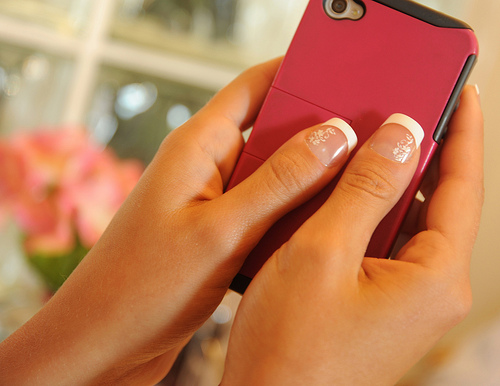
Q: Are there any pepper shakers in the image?
A: No, there are no pepper shakers.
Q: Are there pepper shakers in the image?
A: No, there are no pepper shakers.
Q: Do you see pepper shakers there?
A: No, there are no pepper shakers.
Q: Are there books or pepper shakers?
A: No, there are no pepper shakers or books.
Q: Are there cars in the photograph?
A: No, there are no cars.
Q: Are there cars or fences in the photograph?
A: No, there are no cars or fences.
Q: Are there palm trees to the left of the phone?
A: Yes, there is a palm tree to the left of the phone.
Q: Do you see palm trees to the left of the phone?
A: Yes, there is a palm tree to the left of the phone.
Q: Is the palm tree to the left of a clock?
A: No, the palm tree is to the left of the phone.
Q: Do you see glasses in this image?
A: No, there are no glasses.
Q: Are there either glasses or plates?
A: No, there are no glasses or plates.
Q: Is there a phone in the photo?
A: Yes, there is a phone.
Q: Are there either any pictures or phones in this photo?
A: Yes, there is a phone.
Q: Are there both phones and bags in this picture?
A: No, there is a phone but no bags.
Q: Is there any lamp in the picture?
A: No, there are no lamps.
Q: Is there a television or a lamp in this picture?
A: No, there are no lamps or televisions.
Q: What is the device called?
A: The device is a phone.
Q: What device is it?
A: The device is a phone.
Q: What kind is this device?
A: This is a phone.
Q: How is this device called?
A: This is a phone.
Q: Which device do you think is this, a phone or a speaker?
A: This is a phone.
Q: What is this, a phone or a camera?
A: This is a phone.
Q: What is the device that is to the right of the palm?
A: The device is a phone.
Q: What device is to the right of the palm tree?
A: The device is a phone.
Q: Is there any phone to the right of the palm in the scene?
A: Yes, there is a phone to the right of the palm.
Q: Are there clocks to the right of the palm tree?
A: No, there is a phone to the right of the palm tree.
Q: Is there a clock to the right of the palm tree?
A: No, there is a phone to the right of the palm tree.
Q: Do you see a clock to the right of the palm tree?
A: No, there is a phone to the right of the palm tree.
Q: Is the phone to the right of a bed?
A: No, the phone is to the right of the palm.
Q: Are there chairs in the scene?
A: No, there are no chairs.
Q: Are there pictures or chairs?
A: No, there are no chairs or pictures.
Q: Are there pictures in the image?
A: No, there are no pictures.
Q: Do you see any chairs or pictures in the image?
A: No, there are no pictures or chairs.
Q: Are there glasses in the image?
A: No, there are no glasses.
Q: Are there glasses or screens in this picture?
A: No, there are no glasses or screens.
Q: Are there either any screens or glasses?
A: No, there are no glasses or screens.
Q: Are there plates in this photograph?
A: No, there are no plates.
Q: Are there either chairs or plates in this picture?
A: No, there are no plates or chairs.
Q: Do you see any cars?
A: No, there are no cars.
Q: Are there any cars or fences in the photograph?
A: No, there are no cars or fences.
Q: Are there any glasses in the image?
A: No, there are no glasses.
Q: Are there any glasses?
A: No, there are no glasses.